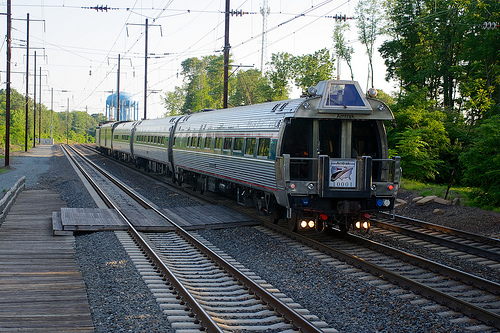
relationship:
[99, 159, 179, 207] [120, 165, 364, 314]
stones are in middle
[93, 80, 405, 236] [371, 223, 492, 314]
train on tracks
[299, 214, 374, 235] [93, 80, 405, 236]
lights are on train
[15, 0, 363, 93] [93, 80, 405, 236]
electric lines are above train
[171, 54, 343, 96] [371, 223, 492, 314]
trees are near tracks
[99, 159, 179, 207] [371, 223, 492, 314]
stones are near tracks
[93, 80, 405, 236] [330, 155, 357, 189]
train has sign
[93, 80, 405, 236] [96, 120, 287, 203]
train has four cars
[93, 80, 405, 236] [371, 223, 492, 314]
train traveling on tracks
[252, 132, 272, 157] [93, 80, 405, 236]
window on side of train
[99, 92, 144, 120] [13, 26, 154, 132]
water tower in distance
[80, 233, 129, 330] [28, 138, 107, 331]
rocks are on side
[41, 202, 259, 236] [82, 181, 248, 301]
board across tracks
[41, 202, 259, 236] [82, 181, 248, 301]
board along side of tracks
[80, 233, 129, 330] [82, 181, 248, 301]
rocks are between tracks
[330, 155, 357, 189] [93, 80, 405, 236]
sign on train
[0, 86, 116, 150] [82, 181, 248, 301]
row of trees alongside tracks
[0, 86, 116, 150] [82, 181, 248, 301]
row of trees are alongside tracks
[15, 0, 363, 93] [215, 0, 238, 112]
electric lines are on pole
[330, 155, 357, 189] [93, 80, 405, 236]
sign in front of train